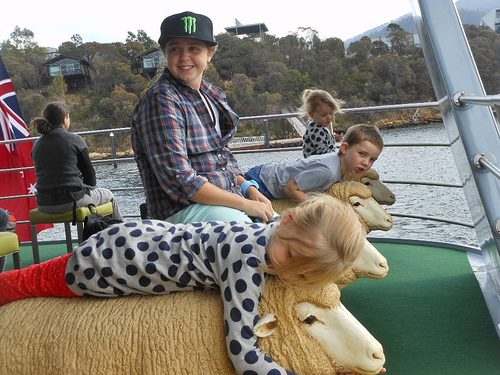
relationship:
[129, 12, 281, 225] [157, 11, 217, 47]
woman wearing ballcap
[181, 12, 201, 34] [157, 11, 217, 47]
logo on ballcap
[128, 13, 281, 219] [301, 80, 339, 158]
woman with kid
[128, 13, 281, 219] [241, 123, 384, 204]
woman with boy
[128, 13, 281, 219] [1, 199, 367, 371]
woman with kid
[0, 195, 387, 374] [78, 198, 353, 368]
child wearing shirt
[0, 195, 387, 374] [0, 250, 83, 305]
child wearing pants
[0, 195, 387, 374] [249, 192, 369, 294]
child has hair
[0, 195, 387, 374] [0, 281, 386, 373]
child lying on sheep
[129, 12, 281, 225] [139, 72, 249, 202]
woman wearing shirt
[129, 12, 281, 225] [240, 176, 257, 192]
woman wearing wristband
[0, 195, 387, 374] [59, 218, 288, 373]
child wearing shirt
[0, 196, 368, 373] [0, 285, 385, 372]
child laying on sheep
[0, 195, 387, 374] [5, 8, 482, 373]
child playing boat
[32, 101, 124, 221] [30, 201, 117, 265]
woman/bench sitting bench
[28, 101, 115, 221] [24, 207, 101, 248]
woman/bench seated bench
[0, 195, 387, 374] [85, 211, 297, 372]
child wearing top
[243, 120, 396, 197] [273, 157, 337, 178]
boy wearing t-shirt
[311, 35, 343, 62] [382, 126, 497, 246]
tree filled water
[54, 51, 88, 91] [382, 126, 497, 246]
house filled water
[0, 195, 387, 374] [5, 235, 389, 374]
child playing on sheep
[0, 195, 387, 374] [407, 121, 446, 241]
child traveling by water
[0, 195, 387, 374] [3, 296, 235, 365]
child laying on something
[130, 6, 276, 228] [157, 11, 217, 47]
person wearing ballcap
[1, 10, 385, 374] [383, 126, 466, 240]
family crossing water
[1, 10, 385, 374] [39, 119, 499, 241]
family enjoying water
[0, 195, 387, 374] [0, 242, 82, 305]
child wearing pants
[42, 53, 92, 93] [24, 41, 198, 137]
house on a hillside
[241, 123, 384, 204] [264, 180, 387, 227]
boy on a statue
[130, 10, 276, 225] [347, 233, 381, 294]
person on a statue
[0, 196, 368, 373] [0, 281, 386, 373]
child on a sheep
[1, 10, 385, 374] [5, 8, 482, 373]
family on a boat